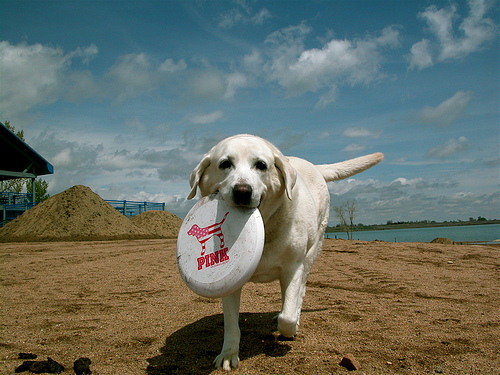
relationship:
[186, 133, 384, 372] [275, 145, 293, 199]
dog has an ear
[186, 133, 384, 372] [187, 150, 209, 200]
dog has an ear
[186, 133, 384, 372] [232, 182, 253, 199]
dog has a nose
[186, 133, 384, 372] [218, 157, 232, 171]
dog has an eye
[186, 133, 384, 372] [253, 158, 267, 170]
dog has an eye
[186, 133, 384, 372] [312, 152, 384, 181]
dog has a tail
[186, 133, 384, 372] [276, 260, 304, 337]
dog has a leg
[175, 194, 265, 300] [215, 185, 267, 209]
frisbee in h mouth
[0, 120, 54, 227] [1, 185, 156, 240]
building behind sand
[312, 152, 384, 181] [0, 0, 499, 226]
tail in sky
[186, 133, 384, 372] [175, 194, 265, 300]
dog holding frisbee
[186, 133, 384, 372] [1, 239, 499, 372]
dog on sand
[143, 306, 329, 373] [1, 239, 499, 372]
shadow on ground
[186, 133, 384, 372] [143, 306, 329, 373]
dog has a shadow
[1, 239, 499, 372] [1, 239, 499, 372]
sand on ground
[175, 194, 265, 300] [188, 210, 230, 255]
frisbee has a dog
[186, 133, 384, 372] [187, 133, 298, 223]
dog has a head